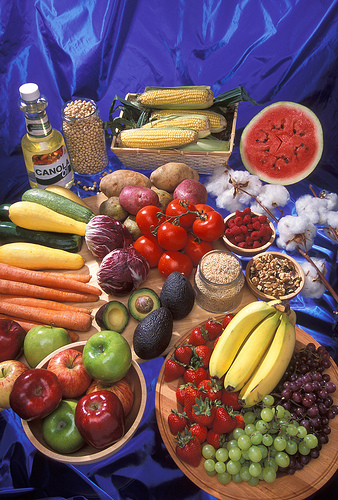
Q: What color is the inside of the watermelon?
A: Pink.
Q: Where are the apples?
A: In the lower left hand corner.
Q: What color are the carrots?
A: Orange.